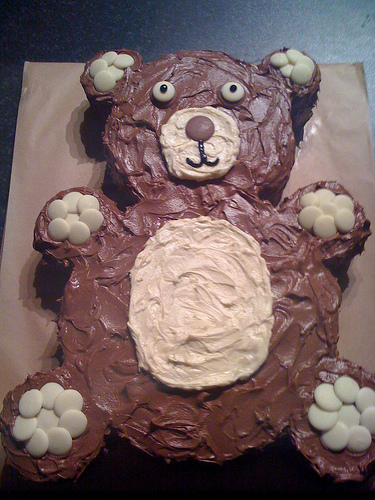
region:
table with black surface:
[0, 0, 373, 47]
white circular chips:
[14, 379, 87, 456]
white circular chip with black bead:
[155, 78, 173, 102]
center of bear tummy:
[130, 216, 274, 387]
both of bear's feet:
[2, 365, 372, 484]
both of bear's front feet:
[31, 183, 371, 264]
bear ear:
[79, 43, 141, 100]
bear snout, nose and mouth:
[159, 107, 242, 178]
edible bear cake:
[2, 46, 371, 482]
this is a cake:
[0, 31, 373, 482]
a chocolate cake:
[1, 31, 372, 498]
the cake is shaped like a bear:
[0, 37, 372, 487]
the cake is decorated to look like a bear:
[3, 41, 373, 474]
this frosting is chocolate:
[131, 404, 197, 442]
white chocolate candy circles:
[9, 381, 90, 456]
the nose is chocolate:
[184, 112, 217, 141]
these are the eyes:
[143, 71, 263, 113]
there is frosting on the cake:
[1, 27, 373, 491]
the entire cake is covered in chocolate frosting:
[1, 30, 372, 491]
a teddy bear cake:
[42, 48, 357, 484]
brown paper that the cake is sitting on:
[10, 44, 93, 195]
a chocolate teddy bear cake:
[49, 48, 373, 474]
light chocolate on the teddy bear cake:
[131, 233, 278, 384]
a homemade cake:
[39, 66, 362, 491]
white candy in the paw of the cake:
[10, 375, 116, 460]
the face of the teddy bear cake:
[149, 68, 273, 197]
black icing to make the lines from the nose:
[183, 133, 218, 176]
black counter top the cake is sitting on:
[59, 15, 352, 55]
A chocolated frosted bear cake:
[2, 42, 373, 490]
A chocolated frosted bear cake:
[0, 38, 370, 492]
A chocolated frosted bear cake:
[5, 41, 369, 492]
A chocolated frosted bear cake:
[0, 43, 372, 486]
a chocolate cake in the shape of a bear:
[3, 30, 373, 498]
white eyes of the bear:
[144, 74, 249, 105]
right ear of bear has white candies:
[257, 42, 329, 106]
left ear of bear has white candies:
[71, 40, 138, 98]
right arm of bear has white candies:
[289, 175, 368, 255]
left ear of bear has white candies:
[27, 179, 120, 262]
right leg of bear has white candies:
[298, 360, 373, 467]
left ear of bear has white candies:
[4, 368, 106, 481]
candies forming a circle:
[7, 376, 89, 461]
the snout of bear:
[156, 103, 246, 183]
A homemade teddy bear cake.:
[0, 38, 372, 494]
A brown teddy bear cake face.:
[73, 37, 319, 207]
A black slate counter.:
[2, 3, 370, 74]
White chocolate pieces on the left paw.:
[43, 183, 118, 257]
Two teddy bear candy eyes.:
[154, 69, 249, 107]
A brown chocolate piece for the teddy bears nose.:
[179, 110, 218, 144]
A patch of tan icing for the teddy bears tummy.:
[122, 211, 280, 394]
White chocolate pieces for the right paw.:
[290, 178, 368, 258]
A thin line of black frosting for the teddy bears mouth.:
[181, 136, 226, 175]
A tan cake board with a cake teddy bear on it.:
[4, 53, 374, 492]